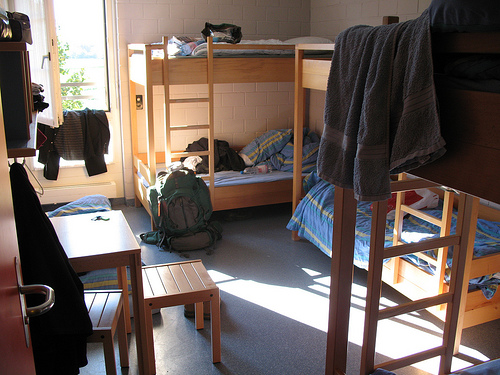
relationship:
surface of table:
[49, 210, 141, 259] [50, 210, 152, 374]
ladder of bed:
[163, 35, 215, 216] [127, 37, 296, 230]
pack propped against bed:
[157, 164, 215, 252] [127, 37, 296, 230]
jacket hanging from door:
[8, 162, 92, 374] [2, 82, 55, 374]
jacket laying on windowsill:
[37, 108, 110, 179] [64, 108, 111, 116]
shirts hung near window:
[0, 9, 33, 148] [51, 0, 111, 114]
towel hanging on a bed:
[316, 22, 405, 203] [324, 24, 498, 371]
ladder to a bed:
[163, 35, 215, 216] [127, 37, 296, 230]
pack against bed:
[157, 164, 215, 252] [127, 37, 296, 230]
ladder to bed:
[163, 35, 215, 216] [127, 37, 296, 230]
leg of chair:
[211, 300, 222, 364] [140, 258, 220, 374]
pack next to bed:
[157, 164, 215, 252] [127, 37, 296, 230]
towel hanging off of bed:
[316, 22, 405, 203] [324, 24, 498, 371]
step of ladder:
[168, 97, 211, 106] [163, 35, 215, 216]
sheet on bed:
[214, 166, 293, 185] [127, 37, 296, 230]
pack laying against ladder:
[157, 164, 215, 252] [163, 35, 215, 216]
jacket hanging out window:
[37, 108, 110, 179] [51, 0, 111, 114]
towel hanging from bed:
[316, 22, 405, 203] [127, 37, 296, 230]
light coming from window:
[54, 1, 110, 112] [51, 0, 111, 114]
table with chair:
[50, 210, 152, 374] [140, 258, 220, 374]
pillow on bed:
[239, 125, 294, 165] [127, 37, 296, 230]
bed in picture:
[127, 37, 296, 230] [0, 2, 497, 374]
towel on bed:
[316, 22, 405, 203] [324, 24, 498, 371]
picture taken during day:
[0, 2, 497, 374] [2, 3, 496, 372]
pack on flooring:
[157, 164, 215, 252] [47, 205, 499, 374]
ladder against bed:
[163, 35, 215, 216] [127, 37, 296, 230]